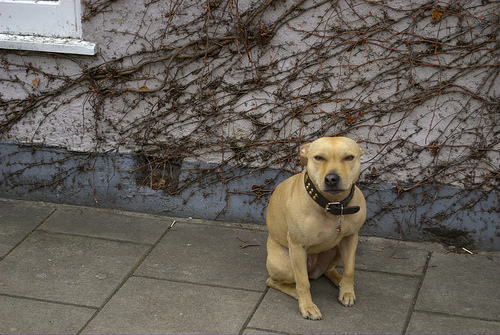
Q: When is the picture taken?
A: Daytime.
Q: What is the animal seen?
A: Dog.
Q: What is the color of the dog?
A: Brown.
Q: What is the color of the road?
A: Grey.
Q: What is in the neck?
A: Belt.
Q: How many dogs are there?
A: One.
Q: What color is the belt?
A: Black.